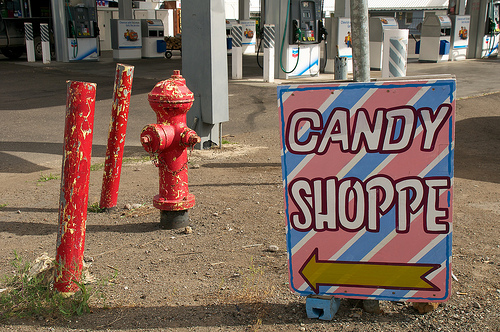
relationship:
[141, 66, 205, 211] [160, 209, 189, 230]
fire hydrant on a base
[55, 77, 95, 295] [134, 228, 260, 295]
pole in ground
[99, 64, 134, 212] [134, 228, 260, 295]
pole in ground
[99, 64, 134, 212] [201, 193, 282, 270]
pole in ground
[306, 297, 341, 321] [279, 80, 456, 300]
blue brick underneath sign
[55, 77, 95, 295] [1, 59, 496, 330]
pole stuck in ground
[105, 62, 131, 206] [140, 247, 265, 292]
pole stuck in ground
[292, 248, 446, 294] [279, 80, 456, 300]
arrow on sign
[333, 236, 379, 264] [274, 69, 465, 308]
stripes on sign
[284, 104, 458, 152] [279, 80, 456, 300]
white letters on sign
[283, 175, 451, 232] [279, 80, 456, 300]
white letters on sign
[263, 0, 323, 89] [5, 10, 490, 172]
gas pump in background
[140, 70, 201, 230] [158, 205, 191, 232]
fire hydrant on base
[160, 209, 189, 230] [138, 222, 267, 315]
base on ground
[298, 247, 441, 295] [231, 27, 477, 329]
arrow on sign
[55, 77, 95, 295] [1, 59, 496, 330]
pole on ground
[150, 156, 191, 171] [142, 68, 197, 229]
chain on hydrant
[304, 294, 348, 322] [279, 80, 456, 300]
blue brick on sign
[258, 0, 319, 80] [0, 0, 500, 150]
gas pump at background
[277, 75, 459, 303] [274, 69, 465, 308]
sign on sign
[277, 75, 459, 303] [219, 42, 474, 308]
sign on sign